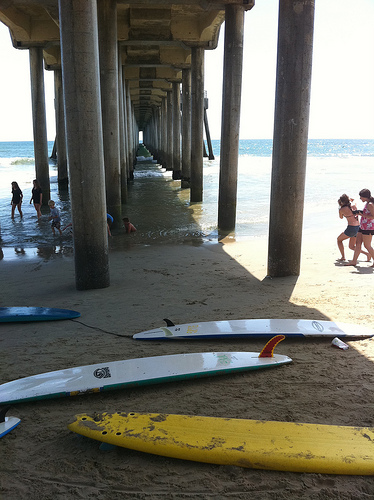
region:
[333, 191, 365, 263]
this is a girl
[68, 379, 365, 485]
this is a surfboard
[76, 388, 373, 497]
the surfboard is yellow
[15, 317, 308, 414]
this is a white surfboard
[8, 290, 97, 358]
this is blue surfboard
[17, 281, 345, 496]
a group of surfboards on sand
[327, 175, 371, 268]
girls walking on the beach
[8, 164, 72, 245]
people standing in water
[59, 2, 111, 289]
A concrete support post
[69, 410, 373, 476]
A yellow surf board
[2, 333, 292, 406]
A white surf board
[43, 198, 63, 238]
A child playing in the water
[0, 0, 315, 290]
The underside of a dock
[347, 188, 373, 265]
A brown haired girl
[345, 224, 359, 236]
A pair of shorts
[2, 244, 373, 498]
A sandy beach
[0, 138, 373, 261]
A large body of water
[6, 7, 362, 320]
under the pier at the beach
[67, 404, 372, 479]
a yellow surfboard on the sand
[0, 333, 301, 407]
a white surfboard on the sand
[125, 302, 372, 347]
a white surfboard on the sand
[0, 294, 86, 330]
a blue surfboard on the sand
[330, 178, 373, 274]
two women walking down the beach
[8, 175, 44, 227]
two women standing in the ocean water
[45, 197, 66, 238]
a child in the ocean water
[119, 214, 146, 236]
a boy in the ocean water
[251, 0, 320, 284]
a support pylon for a pier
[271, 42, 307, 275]
TALL PILLAR FOR BEACH PIER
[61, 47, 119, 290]
TALL PILLAR FOR BEACH PIER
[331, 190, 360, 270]
CHILD RUNNING ON BEACH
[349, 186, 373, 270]
CHILD WALKING ON BEACH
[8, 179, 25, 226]
PERSON WADING IN WATER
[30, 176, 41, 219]
PERSON WADING IN WATER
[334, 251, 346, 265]
FOOT OF RUNNING BEACH CHILD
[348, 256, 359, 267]
FOOT OF WALKING BEACH CHILD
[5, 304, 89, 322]
PART OF BLUE SURF BOARD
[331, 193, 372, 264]
a person on the beach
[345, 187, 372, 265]
a person on the beach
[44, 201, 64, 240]
a person on the beach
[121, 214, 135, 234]
a person on the beach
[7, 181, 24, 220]
a person on the beach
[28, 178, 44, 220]
a person on the beach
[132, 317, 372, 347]
a surfboard on the beach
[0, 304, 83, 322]
a surfboard on the beach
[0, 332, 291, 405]
a surfboard on the beach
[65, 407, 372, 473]
a surfboard on the beach